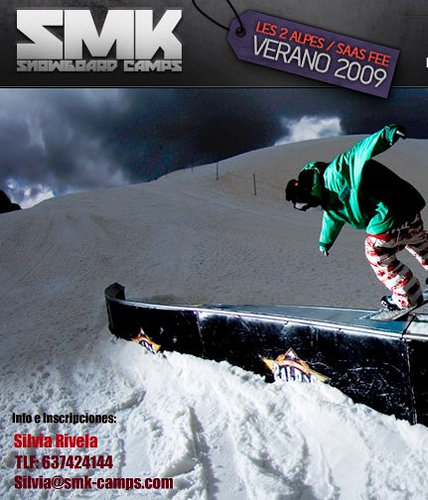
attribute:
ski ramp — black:
[99, 278, 426, 426]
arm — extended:
[352, 121, 405, 167]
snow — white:
[180, 416, 423, 496]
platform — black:
[95, 280, 425, 426]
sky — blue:
[1, 88, 426, 210]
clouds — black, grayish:
[0, 86, 426, 209]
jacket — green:
[296, 125, 427, 258]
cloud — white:
[268, 113, 340, 143]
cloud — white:
[4, 179, 54, 213]